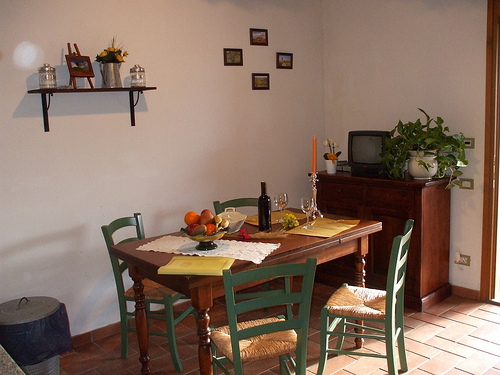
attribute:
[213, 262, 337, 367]
chair — green, wood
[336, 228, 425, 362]
chair — wood, green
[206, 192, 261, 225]
chair — green, wood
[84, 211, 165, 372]
chair — wood, green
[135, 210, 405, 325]
table — wooden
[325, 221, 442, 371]
chair — green, brown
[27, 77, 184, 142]
shelf — hanging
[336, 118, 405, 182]
tv — small, boxy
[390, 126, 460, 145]
plant — green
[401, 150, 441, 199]
vase — white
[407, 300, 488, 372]
floor — tiled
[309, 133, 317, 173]
candle stick — orange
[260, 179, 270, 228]
bottle — of wine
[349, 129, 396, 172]
t.v. — black, small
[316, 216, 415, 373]
dining chair — green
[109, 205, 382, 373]
table — wooden, brown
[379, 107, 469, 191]
plant — potted, green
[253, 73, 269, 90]
picture frame — small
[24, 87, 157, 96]
shelf — long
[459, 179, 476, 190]
switch — light switch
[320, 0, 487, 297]
wall — white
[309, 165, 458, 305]
cabinet — brown, large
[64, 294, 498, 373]
floor — brick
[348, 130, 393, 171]
tv — black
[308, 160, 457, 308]
table — side table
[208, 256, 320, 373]
chair — green, dining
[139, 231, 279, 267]
placemat — white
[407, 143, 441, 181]
pot — white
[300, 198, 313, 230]
glass — wine glass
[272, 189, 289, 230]
glass — wine glass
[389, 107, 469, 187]
plant — Potted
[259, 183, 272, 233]
bottle — of wine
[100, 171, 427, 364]
chairs — four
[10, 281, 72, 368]
can — trash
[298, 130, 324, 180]
candle — orange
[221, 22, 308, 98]
pictures — four, small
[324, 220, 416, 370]
chair — green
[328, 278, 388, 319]
seat — wicker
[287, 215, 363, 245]
placemat — yellow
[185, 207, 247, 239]
bowl — one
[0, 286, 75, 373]
can — tin, trash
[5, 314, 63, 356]
bag — black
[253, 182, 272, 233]
bottle — black, glass, wine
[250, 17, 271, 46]
frame — picture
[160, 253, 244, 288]
placemat — yellow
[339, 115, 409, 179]
tv — black, small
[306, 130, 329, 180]
candlestick — orange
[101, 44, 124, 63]
flowers — yellow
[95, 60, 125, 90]
can — tin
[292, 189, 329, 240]
glass — wine